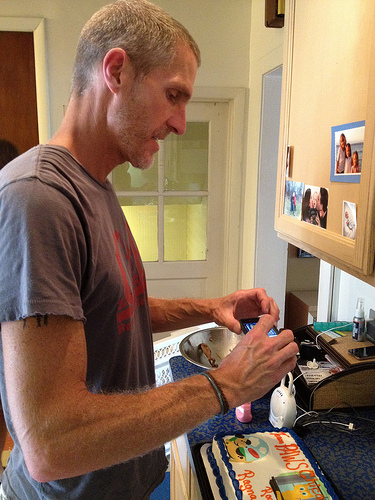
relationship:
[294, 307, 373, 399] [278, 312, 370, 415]
things are inside of box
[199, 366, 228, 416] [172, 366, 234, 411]
wrist band on wrist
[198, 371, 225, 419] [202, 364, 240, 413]
wrist band on wrist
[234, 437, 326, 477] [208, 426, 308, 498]
icing on cake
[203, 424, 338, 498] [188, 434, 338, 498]
cake on tray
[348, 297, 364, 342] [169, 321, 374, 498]
bottle on counter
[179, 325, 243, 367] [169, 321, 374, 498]
bowl on counter